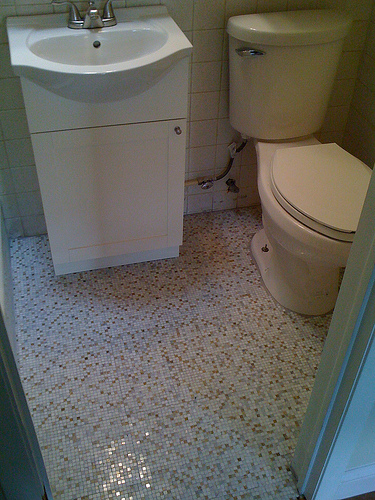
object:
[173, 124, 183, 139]
knob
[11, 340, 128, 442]
tile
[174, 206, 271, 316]
tile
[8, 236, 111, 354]
tile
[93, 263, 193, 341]
tile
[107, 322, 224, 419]
tile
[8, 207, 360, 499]
floor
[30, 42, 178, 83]
lip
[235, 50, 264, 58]
handle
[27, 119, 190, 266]
cabinet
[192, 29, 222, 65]
tile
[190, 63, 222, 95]
tile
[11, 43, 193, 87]
curved edge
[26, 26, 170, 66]
sink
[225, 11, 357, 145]
tank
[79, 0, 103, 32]
faucet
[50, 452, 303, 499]
doorway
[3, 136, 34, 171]
tile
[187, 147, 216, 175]
tile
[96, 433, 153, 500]
light reflection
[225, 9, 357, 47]
lid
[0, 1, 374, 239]
wall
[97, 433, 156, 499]
light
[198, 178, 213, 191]
valve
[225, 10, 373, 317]
toilet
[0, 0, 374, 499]
bathroom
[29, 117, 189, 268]
door